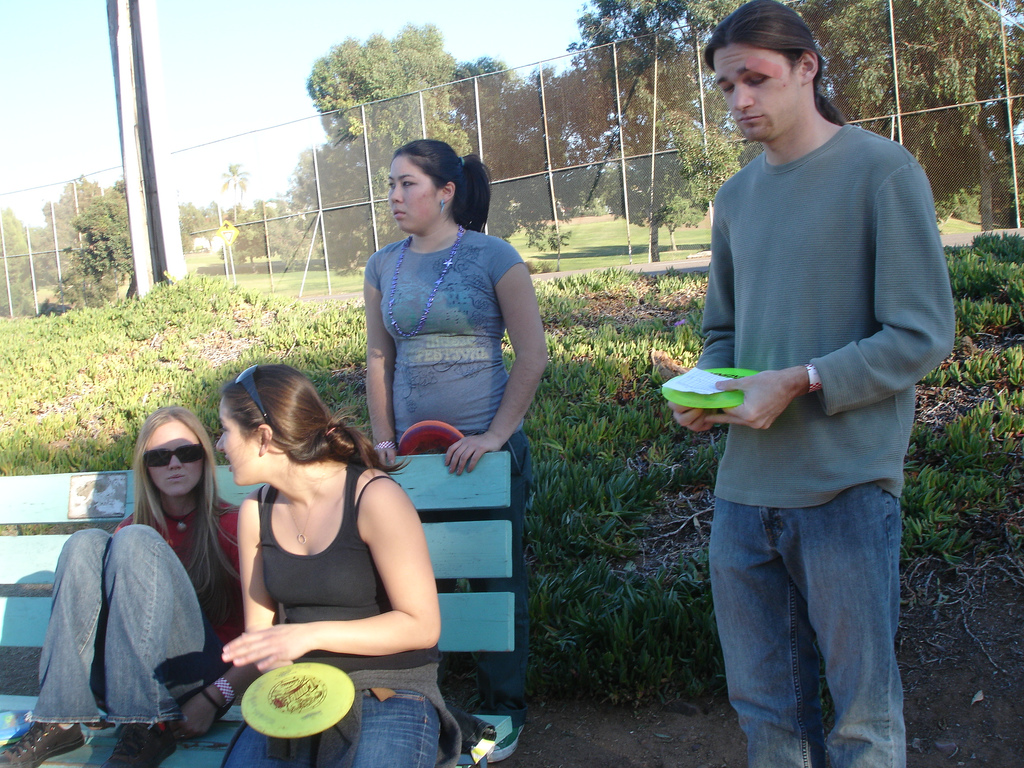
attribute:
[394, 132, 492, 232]
hair — brown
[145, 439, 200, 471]
glasses — black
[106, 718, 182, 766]
shoe — black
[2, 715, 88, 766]
shoe — black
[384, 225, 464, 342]
necklace — purple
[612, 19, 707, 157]
fence section — metal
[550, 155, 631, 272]
fence section — metal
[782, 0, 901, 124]
fence section — metal